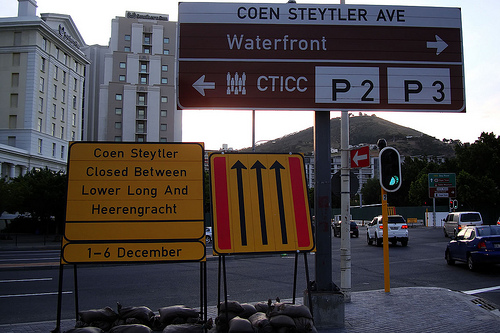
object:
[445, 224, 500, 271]
car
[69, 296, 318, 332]
sandbags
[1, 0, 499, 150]
sky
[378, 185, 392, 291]
pole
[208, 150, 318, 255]
sign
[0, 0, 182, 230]
building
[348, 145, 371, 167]
sign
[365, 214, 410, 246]
car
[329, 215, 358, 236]
car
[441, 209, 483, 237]
car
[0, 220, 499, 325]
street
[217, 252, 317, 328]
post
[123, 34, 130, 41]
window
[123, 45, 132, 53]
window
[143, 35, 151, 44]
window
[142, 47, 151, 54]
window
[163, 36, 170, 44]
window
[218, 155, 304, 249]
signs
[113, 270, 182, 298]
street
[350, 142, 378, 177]
arrow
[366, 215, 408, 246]
vehicle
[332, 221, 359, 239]
vehicle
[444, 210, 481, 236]
vehicle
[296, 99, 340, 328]
pole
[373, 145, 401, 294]
light signal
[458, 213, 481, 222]
rear window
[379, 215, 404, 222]
rear window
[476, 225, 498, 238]
rear window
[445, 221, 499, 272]
vehicle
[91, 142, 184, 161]
black writing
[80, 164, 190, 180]
black writing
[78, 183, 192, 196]
black writing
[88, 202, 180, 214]
black writing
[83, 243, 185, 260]
black writing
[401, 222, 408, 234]
light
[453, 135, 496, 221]
trees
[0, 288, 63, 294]
lines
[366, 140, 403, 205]
signal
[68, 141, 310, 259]
yellow post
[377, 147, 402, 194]
traffic light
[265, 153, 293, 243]
black arrow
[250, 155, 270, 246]
black arrow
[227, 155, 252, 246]
black arrow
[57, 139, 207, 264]
sign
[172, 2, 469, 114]
sign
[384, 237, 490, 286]
street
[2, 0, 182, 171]
tall building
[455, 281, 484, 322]
drainage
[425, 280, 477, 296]
asphalt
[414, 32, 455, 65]
arrow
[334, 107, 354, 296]
pole